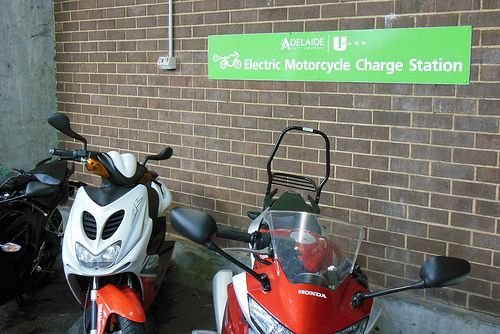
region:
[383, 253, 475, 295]
The bike has a mirror.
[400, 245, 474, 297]
The mirror is black.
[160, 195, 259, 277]
The bike has a mirror.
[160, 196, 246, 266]
The mirror is black.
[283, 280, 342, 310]
The bike is a Honda.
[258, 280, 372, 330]
The bike is red.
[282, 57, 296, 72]
The letter is white.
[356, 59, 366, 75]
The letter is white.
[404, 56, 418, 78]
The letter is white.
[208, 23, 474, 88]
this is a charging station for electric motorcycles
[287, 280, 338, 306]
this motorcycle is made by Honda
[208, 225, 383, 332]
this motorcycle has red and white detailing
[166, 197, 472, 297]
this motorcycle has widely placed rear-view mirrors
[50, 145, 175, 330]
this motorcycle has white and red detailing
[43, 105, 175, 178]
the rear-view mirrors on this bike are not widely placed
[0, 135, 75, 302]
this motorcycle is black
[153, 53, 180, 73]
this appears to be the place to plug in for a charge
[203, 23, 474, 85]
the sign is green with white lettering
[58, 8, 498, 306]
the wall is made of brick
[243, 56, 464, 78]
Words "electric motorcycle charge station" on sign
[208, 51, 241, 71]
drawing of motorcycle on sign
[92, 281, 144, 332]
red tire cover on bike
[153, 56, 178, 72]
electrical outlet on wall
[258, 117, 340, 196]
black rack on back of Honda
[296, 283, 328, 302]
"HONDA" on red and white bike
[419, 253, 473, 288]
driver's side mirror on Honda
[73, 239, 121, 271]
headlamp on white bike on left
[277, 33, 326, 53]
"Adelaide" on sign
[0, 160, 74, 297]
part of black bike on far left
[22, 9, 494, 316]
motorcycles near a wall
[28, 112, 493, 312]
these motorcycles are being charged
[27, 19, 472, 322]
the motorcycles are electric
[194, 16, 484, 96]
this sign is green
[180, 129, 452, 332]
this motorcycle is red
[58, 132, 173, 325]
the motorcycle is white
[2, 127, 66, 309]
his motorcycle is black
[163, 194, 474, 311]
two black rearview mirrors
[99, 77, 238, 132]
a red brick wall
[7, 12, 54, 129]
a solid stone gray wall